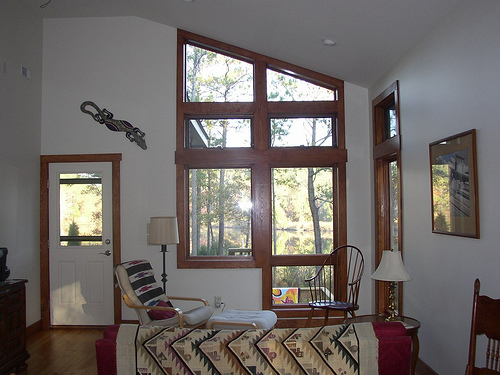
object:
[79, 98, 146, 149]
gecko figurine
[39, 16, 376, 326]
wall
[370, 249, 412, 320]
lamp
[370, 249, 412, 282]
lamp shade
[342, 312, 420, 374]
end table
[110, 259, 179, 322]
blanket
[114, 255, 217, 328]
chair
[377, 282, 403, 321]
base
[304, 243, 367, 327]
chair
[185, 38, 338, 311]
window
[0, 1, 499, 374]
living room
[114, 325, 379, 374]
blanket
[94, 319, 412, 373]
couch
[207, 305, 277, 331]
ottoman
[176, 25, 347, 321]
frame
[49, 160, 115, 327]
door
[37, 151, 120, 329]
door frame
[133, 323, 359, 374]
design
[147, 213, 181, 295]
floor lamp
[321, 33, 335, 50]
recessed light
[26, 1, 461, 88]
ceiling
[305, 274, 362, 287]
arms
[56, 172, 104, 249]
window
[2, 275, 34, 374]
chest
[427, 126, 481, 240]
picture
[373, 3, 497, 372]
wall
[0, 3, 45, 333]
wall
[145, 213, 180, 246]
lamp shade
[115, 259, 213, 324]
cushion